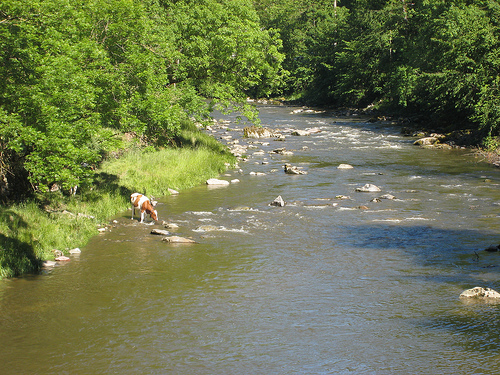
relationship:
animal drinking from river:
[130, 193, 158, 224] [6, 97, 495, 374]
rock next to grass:
[187, 96, 452, 210] [57, 83, 246, 228]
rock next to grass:
[67, 245, 84, 258] [57, 83, 246, 228]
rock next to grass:
[42, 248, 81, 267] [57, 83, 246, 228]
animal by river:
[130, 193, 158, 224] [218, 110, 405, 303]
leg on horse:
[129, 204, 139, 220] [123, 189, 168, 234]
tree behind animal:
[20, 14, 246, 204] [112, 177, 166, 247]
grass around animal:
[0, 130, 232, 276] [120, 187, 168, 229]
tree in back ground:
[0, 0, 500, 203] [11, 18, 486, 178]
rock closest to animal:
[149, 211, 215, 244] [114, 179, 193, 264]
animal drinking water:
[128, 192, 159, 225] [142, 92, 390, 347]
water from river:
[142, 92, 390, 347] [6, 97, 495, 374]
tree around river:
[0, 0, 500, 203] [6, 97, 495, 374]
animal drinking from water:
[130, 193, 158, 224] [189, 100, 484, 367]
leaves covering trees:
[13, 5, 258, 176] [372, 7, 497, 139]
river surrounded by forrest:
[78, 55, 495, 360] [0, 4, 285, 284]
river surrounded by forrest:
[78, 55, 495, 360] [253, 4, 497, 201]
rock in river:
[458, 285, 498, 305] [6, 97, 495, 374]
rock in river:
[187, 96, 452, 210] [6, 97, 495, 374]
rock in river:
[160, 233, 197, 244] [6, 97, 495, 374]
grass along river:
[0, 147, 239, 275] [6, 97, 495, 374]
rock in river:
[187, 96, 452, 210] [1, 67, 498, 371]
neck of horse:
[142, 202, 159, 218] [125, 181, 165, 233]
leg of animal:
[127, 202, 162, 239] [130, 193, 158, 224]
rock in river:
[288, 128, 304, 137] [6, 97, 495, 374]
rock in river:
[458, 287, 500, 300] [196, 82, 476, 350]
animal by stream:
[130, 193, 158, 224] [185, 254, 300, 322]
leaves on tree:
[13, 5, 258, 176] [6, 2, 298, 239]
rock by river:
[42, 248, 81, 267] [6, 97, 495, 374]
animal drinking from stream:
[130, 193, 158, 224] [0, 99, 498, 372]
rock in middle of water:
[187, 96, 452, 210] [191, 245, 355, 369]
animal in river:
[130, 193, 158, 224] [6, 97, 495, 374]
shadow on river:
[343, 216, 498, 356] [6, 97, 495, 374]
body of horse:
[130, 190, 146, 209] [129, 186, 161, 226]